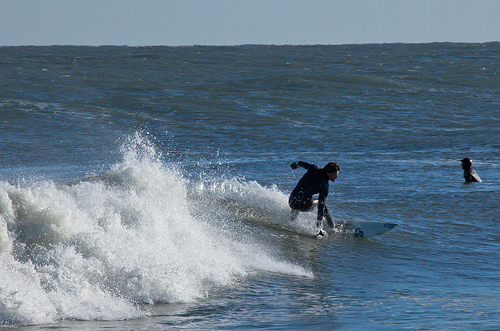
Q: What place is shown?
A: It is an ocean.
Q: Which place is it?
A: It is an ocean.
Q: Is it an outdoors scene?
A: Yes, it is outdoors.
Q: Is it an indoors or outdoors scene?
A: It is outdoors.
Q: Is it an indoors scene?
A: No, it is outdoors.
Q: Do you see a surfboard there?
A: Yes, there is a surfboard.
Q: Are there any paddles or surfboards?
A: Yes, there is a surfboard.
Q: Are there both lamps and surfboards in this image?
A: No, there is a surfboard but no lamps.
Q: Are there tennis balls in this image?
A: No, there are no tennis balls.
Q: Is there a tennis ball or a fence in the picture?
A: No, there are no tennis balls or fences.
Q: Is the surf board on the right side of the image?
A: Yes, the surf board is on the right of the image.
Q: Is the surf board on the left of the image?
A: No, the surf board is on the right of the image.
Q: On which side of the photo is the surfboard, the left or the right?
A: The surfboard is on the right of the image.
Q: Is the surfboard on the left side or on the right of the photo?
A: The surfboard is on the right of the image.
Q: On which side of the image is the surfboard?
A: The surfboard is on the right of the image.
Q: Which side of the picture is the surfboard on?
A: The surfboard is on the right of the image.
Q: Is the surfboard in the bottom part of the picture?
A: Yes, the surfboard is in the bottom of the image.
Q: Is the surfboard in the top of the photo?
A: No, the surfboard is in the bottom of the image.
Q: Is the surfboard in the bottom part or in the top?
A: The surfboard is in the bottom of the image.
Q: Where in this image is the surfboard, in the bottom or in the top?
A: The surfboard is in the bottom of the image.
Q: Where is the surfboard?
A: The surfboard is in the water.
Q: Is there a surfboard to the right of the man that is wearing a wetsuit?
A: Yes, there is a surfboard to the right of the man.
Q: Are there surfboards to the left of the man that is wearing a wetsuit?
A: No, the surfboard is to the right of the man.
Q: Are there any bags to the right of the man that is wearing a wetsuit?
A: No, there is a surfboard to the right of the man.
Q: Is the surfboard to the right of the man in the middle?
A: Yes, the surfboard is to the right of the man.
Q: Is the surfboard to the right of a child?
A: No, the surfboard is to the right of the man.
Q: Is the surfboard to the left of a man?
A: No, the surfboard is to the right of a man.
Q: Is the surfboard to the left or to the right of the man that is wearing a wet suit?
A: The surfboard is to the right of the man.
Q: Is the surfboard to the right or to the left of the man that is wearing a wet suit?
A: The surfboard is to the right of the man.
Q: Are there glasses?
A: No, there are no glasses.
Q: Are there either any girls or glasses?
A: No, there are no glasses or girls.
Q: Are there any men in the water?
A: Yes, there is a man in the water.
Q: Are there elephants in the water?
A: No, there is a man in the water.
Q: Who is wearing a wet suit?
A: The man is wearing a wet suit.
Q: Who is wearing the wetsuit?
A: The man is wearing a wet suit.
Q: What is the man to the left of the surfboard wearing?
A: The man is wearing a wet suit.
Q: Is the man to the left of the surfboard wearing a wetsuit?
A: Yes, the man is wearing a wetsuit.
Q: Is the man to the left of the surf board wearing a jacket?
A: No, the man is wearing a wetsuit.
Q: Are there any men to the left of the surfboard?
A: Yes, there is a man to the left of the surfboard.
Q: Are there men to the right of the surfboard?
A: No, the man is to the left of the surfboard.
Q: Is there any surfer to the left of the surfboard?
A: No, there is a man to the left of the surfboard.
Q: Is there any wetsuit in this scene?
A: Yes, there is a wetsuit.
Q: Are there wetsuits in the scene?
A: Yes, there is a wetsuit.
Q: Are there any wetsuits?
A: Yes, there is a wetsuit.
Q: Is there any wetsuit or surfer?
A: Yes, there is a wetsuit.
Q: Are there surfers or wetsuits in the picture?
A: Yes, there is a wetsuit.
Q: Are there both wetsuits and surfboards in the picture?
A: Yes, there are both a wetsuit and a surfboard.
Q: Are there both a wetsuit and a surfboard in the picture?
A: Yes, there are both a wetsuit and a surfboard.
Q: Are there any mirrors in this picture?
A: No, there are no mirrors.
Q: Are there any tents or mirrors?
A: No, there are no mirrors or tents.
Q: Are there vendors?
A: No, there are no vendors.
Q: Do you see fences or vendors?
A: No, there are no vendors or fences.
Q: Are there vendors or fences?
A: No, there are no vendors or fences.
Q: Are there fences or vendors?
A: No, there are no vendors or fences.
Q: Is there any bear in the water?
A: No, there is a man in the water.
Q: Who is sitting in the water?
A: The man is sitting in the water.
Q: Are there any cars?
A: No, there are no cars.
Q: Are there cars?
A: No, there are no cars.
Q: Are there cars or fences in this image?
A: No, there are no cars or fences.